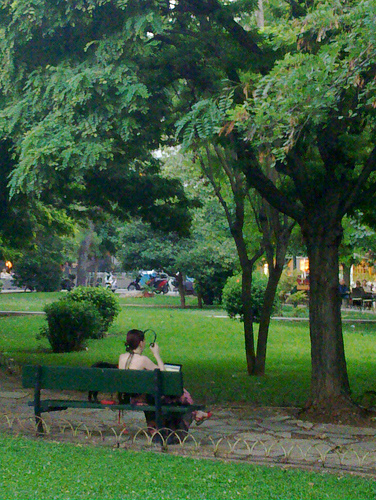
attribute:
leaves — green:
[217, 82, 237, 113]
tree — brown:
[163, 2, 374, 412]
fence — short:
[6, 408, 374, 471]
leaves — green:
[34, 202, 78, 238]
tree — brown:
[0, 54, 200, 248]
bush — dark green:
[35, 297, 102, 352]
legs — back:
[72, 388, 110, 414]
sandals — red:
[190, 409, 213, 425]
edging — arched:
[2, 412, 374, 465]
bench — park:
[21, 360, 206, 452]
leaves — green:
[0, 1, 165, 202]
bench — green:
[17, 337, 259, 476]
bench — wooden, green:
[20, 360, 206, 437]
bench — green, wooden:
[17, 353, 212, 419]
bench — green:
[13, 359, 211, 444]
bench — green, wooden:
[19, 340, 220, 442]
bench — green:
[10, 351, 196, 431]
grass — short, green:
[179, 307, 222, 358]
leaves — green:
[214, 61, 314, 142]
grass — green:
[6, 441, 373, 495]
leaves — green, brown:
[0, 0, 373, 231]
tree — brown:
[0, 1, 374, 425]